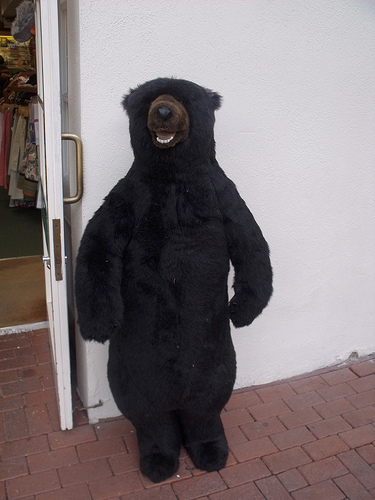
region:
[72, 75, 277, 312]
Stuffed bear's head and shoulders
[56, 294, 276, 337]
Stuffed bear's paws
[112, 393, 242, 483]
Stuffed bear's legs and feet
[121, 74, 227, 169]
Bear's smiling face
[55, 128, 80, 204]
Handle to door leading to store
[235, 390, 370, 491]
Brick sidewalk that stuffed bear stands on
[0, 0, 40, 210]
Items for sale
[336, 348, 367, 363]
Crack in the plaster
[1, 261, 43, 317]
Wooden floor in store's entrance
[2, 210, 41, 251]
Green carpeting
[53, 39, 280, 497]
the giant stuffed teddybear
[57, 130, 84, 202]
the handle of the door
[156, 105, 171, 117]
the nose of the bear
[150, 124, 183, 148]
the mouth of the bear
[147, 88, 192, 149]
the snout of the bear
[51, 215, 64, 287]
the metal plate on the door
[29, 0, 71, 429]
the open white door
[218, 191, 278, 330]
the bent arm of the bear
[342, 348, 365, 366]
the hole in the wall behind the bear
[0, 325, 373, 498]
the brick floor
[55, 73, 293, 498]
a stuffed bear sitting outside a door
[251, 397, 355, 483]
a red brick ground covering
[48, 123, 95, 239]
a brass handle on a door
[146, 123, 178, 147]
the mouth with teeth on the stuffed bear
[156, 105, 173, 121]
a black nose on the stuffed bear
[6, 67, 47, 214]
a rack of clothes hanging inside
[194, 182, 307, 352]
the arm of the stuffed bear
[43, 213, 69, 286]
a brass catch plate on the door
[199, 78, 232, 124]
the ear of the stuffed bear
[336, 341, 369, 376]
a cracked hole in the wall by the ground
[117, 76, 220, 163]
a smiling bear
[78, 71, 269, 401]
a black bear against the wall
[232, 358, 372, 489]
sidewalk made of brick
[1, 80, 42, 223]
clothes on a rack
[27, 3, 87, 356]
an open white door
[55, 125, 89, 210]
a silver door handle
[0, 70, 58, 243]
clothes in a store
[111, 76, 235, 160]
a black bear with a brown nose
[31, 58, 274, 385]
a bear standing by the door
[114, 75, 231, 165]
a bear with white teeth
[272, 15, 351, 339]
portion of solid white wall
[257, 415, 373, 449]
portion of dark red tile on the ground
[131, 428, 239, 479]
pair of black teddy bear feet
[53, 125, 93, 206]
large silver door opener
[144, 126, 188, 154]
pearly white teddy bear's teeth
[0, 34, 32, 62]
yellow clothes folded on shelf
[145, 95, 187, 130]
black teddy bear's nose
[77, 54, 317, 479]
large black teddy bear standing tall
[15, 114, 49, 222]
multi colored garment with flower pattern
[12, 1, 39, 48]
gray garment hanging on door